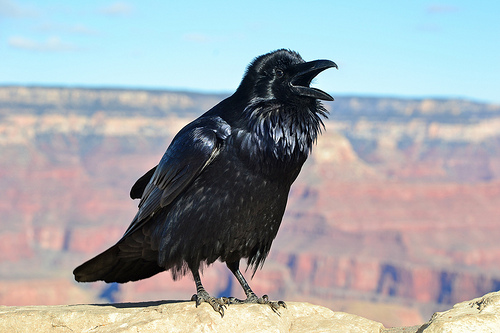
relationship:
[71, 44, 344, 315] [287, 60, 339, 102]
bird has beak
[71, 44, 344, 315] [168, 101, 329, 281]
bird has feathers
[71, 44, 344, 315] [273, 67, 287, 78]
bird has eye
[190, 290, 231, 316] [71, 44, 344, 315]
foog of bird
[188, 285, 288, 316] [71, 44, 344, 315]
feet of bird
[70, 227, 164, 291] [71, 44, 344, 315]
tail of bird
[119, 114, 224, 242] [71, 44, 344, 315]
wing of bird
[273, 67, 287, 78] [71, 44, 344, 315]
eye of bird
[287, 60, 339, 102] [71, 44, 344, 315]
beak of bird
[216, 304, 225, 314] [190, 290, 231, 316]
nail of foog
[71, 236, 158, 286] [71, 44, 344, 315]
tail feathers of bird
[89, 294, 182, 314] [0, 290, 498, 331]
shadow on rock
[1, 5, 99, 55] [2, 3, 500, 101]
cloud in sky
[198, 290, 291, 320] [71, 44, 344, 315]
claws of bird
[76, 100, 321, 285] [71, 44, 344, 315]
feathers of bird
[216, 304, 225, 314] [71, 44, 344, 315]
nail of bird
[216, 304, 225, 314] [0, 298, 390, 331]
nail gripping rock